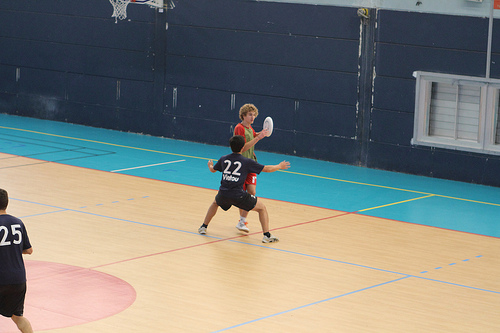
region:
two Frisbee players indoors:
[195, 100, 290, 246]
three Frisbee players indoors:
[0, 100, 292, 331]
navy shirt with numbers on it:
[214, 152, 264, 191]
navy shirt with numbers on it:
[0, 210, 32, 285]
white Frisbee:
[261, 115, 274, 138]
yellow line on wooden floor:
[1, 125, 498, 216]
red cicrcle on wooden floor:
[1, 257, 137, 331]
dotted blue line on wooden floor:
[415, 249, 489, 276]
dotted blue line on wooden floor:
[76, 190, 151, 212]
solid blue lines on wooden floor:
[6, 193, 498, 331]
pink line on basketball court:
[105, 228, 185, 261]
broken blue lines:
[423, 233, 485, 275]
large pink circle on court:
[51, 252, 215, 330]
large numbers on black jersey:
[6, 220, 38, 247]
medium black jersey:
[208, 151, 271, 200]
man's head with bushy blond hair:
[231, 97, 261, 120]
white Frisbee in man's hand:
[263, 110, 288, 139]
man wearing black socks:
[253, 223, 297, 246]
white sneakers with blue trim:
[245, 230, 301, 255]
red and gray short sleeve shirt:
[237, 125, 277, 165]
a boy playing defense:
[200, 131, 284, 245]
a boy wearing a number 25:
[0, 177, 52, 332]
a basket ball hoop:
[86, 0, 181, 38]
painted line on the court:
[7, 122, 167, 215]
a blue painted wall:
[192, 11, 346, 150]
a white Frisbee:
[261, 110, 284, 144]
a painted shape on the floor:
[0, 252, 150, 332]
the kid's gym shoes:
[197, 214, 281, 250]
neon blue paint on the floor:
[337, 169, 483, 226]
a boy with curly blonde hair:
[234, 99, 260, 127]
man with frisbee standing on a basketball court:
[227, 102, 274, 234]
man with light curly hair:
[237, 100, 258, 120]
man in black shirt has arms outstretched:
[196, 136, 288, 246]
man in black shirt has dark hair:
[226, 132, 246, 152]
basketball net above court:
[108, 0, 133, 20]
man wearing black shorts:
[1, 187, 39, 331]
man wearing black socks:
[262, 231, 272, 239]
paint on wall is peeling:
[351, 7, 386, 163]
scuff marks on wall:
[17, 90, 69, 120]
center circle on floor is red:
[15, 257, 139, 332]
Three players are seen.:
[5, 122, 295, 283]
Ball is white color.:
[262, 115, 285, 145]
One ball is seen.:
[260, 115, 287, 142]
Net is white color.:
[105, 0, 151, 26]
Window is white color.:
[406, 67, 494, 178]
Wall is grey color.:
[150, 22, 346, 89]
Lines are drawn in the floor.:
[46, 127, 306, 329]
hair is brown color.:
[240, 100, 255, 117]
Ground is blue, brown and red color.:
[15, 136, 225, 312]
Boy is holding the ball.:
[232, 96, 277, 146]